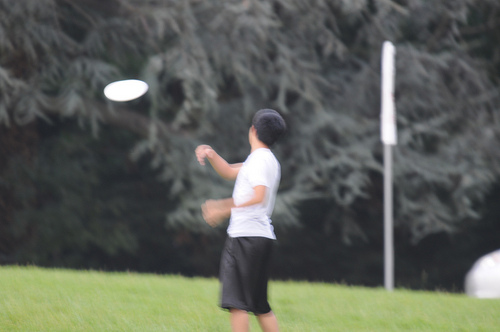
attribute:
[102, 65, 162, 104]
frisbee — white, flying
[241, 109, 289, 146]
hair — black, short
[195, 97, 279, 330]
boy — standing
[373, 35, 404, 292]
post — metal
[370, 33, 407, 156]
sign — white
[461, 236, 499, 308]
rock — white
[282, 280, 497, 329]
grass — green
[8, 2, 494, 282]
foliage — green, dense, large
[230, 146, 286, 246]
shirt — white, plain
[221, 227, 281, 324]
shorts — black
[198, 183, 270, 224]
arm — blurry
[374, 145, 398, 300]
pole — tall, standing, grey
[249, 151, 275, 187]
sleeves — short